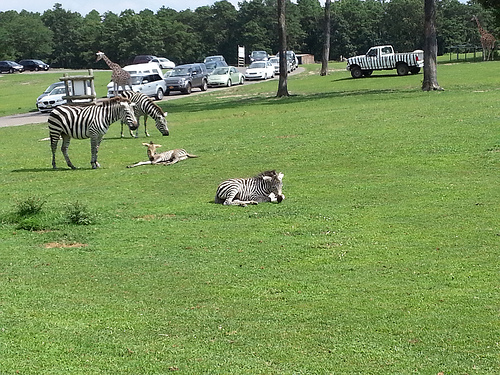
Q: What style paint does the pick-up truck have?
A: Black and white stripes, like a zebra.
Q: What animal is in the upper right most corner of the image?
A: A giraffe.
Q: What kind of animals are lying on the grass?
A: Zebras.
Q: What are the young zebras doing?
A: Lying in the grass.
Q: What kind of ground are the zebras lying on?
A: Grass.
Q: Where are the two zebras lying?
A: On the grass.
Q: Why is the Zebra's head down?
A: It's eating grass.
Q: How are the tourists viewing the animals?
A: From cars.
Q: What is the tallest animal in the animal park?
A: A giraffe.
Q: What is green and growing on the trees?
A: Green leaves.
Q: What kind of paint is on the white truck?
A: Zebra stripes.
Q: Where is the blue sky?
A: Above the trees.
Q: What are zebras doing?
A: Standing.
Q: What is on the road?
A: Cars.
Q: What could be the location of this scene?
A: Wildlife refuge.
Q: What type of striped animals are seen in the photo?
A: Zebras.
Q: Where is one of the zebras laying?
A: On ground.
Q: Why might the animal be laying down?
A: Resting.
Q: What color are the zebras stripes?
A: Black and white.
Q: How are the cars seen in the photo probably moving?
A: Slowly.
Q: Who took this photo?
A: Photographer.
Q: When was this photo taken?
A: Daytime.